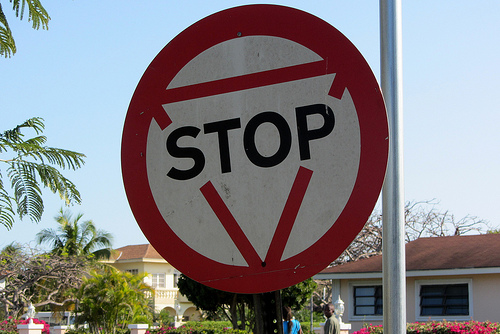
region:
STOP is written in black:
[163, 127, 325, 167]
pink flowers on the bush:
[415, 323, 488, 332]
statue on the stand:
[26, 298, 43, 321]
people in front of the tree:
[281, 304, 346, 331]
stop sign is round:
[165, 80, 360, 285]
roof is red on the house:
[431, 231, 490, 273]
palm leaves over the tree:
[6, 116, 68, 204]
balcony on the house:
[150, 277, 199, 316]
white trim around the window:
[403, 282, 428, 308]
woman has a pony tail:
[281, 322, 302, 330]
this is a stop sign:
[7, 18, 477, 315]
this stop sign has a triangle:
[113, 29, 394, 273]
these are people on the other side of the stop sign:
[275, 288, 336, 332]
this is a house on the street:
[312, 232, 499, 332]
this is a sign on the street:
[124, 11, 389, 306]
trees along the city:
[5, 219, 151, 319]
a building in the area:
[103, 232, 186, 316]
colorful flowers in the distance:
[3, 307, 50, 332]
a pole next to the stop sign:
[373, 8, 430, 323]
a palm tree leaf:
[5, 115, 88, 246]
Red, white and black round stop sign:
[122, 4, 392, 294]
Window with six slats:
[414, 279, 472, 318]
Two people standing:
[277, 302, 341, 332]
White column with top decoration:
[14, 300, 44, 332]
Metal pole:
[379, 0, 410, 331]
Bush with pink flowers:
[349, 318, 499, 333]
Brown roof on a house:
[314, 230, 497, 277]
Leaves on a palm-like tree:
[0, 113, 90, 233]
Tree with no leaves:
[0, 245, 90, 319]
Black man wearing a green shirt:
[321, 303, 341, 330]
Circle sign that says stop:
[121, 5, 391, 293]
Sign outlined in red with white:
[114, 3, 392, 307]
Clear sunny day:
[417, 18, 495, 118]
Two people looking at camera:
[283, 298, 340, 329]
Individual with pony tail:
[280, 305, 310, 330]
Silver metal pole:
[366, 0, 419, 330]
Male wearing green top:
[316, 298, 347, 329]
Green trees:
[13, 208, 136, 329]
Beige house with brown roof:
[325, 227, 496, 323]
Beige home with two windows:
[317, 225, 497, 328]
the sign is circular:
[95, 4, 384, 319]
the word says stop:
[140, 76, 346, 183]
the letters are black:
[150, 92, 361, 188]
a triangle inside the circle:
[145, 45, 352, 254]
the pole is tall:
[352, 4, 428, 325]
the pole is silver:
[349, 9, 427, 321]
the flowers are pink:
[335, 300, 496, 332]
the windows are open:
[404, 279, 490, 322]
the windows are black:
[405, 278, 478, 320]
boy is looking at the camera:
[306, 290, 348, 331]